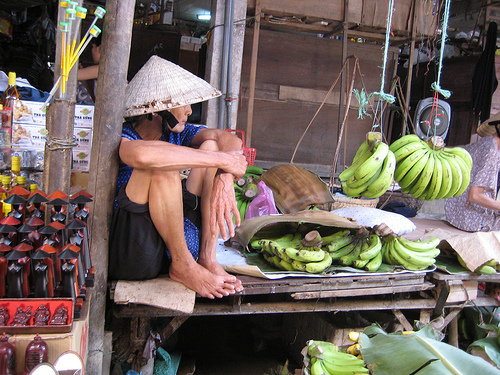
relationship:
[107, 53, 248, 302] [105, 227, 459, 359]
man sitting on table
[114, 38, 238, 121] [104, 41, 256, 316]
hat on head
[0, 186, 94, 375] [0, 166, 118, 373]
box in box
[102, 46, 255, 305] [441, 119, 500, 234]
arm of woman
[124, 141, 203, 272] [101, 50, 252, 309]
leg of woman